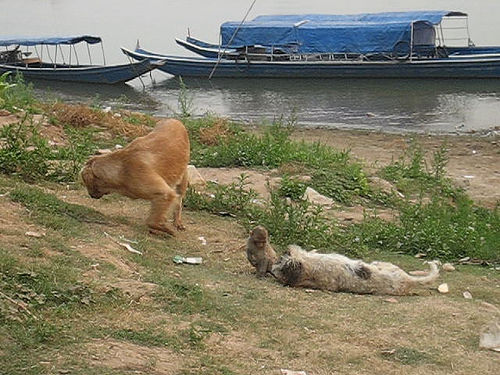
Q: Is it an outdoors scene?
A: Yes, it is outdoors.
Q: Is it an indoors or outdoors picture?
A: It is outdoors.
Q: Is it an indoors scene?
A: No, it is outdoors.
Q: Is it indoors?
A: No, it is outdoors.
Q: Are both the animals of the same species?
A: Yes, all the animals are dogs.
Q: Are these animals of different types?
A: No, all the animals are dogs.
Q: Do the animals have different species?
A: No, all the animals are dogs.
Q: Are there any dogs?
A: Yes, there is a dog.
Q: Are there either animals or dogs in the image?
A: Yes, there is a dog.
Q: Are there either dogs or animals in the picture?
A: Yes, there is a dog.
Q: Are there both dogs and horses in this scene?
A: No, there is a dog but no horses.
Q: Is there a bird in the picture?
A: No, there are no birds.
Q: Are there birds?
A: No, there are no birds.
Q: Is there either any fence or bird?
A: No, there are no birds or fences.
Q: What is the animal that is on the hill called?
A: The animal is a dog.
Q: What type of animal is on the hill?
A: The animal is a dog.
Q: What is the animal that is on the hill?
A: The animal is a dog.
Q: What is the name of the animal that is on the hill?
A: The animal is a dog.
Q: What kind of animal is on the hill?
A: The animal is a dog.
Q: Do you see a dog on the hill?
A: Yes, there is a dog on the hill.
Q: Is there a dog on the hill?
A: Yes, there is a dog on the hill.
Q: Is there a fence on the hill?
A: No, there is a dog on the hill.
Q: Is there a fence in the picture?
A: No, there are no fences.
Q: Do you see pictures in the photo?
A: No, there are no pictures.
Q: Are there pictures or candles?
A: No, there are no pictures or candles.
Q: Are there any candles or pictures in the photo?
A: No, there are no pictures or candles.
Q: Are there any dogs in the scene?
A: Yes, there is a dog.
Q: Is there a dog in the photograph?
A: Yes, there is a dog.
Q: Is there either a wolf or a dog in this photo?
A: Yes, there is a dog.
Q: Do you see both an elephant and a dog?
A: No, there is a dog but no elephants.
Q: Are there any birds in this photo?
A: No, there are no birds.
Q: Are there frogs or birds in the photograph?
A: No, there are no birds or frogs.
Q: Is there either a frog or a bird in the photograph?
A: No, there are no birds or frogs.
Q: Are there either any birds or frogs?
A: No, there are no birds or frogs.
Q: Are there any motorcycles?
A: No, there are no motorcycles.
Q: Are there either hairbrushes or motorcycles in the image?
A: No, there are no motorcycles or hairbrushes.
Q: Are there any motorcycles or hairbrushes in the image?
A: No, there are no motorcycles or hairbrushes.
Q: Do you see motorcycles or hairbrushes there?
A: No, there are no motorcycles or hairbrushes.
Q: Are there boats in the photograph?
A: Yes, there is a boat.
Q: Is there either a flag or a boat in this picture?
A: Yes, there is a boat.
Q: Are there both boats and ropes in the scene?
A: Yes, there are both a boat and a rope.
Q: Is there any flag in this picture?
A: No, there are no flags.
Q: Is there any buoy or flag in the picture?
A: No, there are no flags or buoys.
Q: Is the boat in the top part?
A: Yes, the boat is in the top of the image.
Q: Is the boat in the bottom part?
A: No, the boat is in the top of the image.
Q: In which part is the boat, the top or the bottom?
A: The boat is in the top of the image.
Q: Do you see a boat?
A: Yes, there is a boat.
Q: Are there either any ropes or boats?
A: Yes, there is a boat.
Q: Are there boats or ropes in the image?
A: Yes, there is a boat.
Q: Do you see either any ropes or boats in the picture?
A: Yes, there is a boat.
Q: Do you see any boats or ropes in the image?
A: Yes, there is a boat.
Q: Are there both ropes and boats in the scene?
A: Yes, there are both a boat and a rope.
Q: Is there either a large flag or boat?
A: Yes, there is a large boat.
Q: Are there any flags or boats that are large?
A: Yes, the boat is large.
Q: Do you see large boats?
A: Yes, there is a large boat.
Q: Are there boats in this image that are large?
A: Yes, there is a boat that is large.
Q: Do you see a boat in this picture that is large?
A: Yes, there is a boat that is large.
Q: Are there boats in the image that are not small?
A: Yes, there is a large boat.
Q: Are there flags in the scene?
A: No, there are no flags.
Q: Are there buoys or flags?
A: No, there are no flags or buoys.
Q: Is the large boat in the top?
A: Yes, the boat is in the top of the image.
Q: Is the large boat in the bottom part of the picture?
A: No, the boat is in the top of the image.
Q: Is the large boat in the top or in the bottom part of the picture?
A: The boat is in the top of the image.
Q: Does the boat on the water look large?
A: Yes, the boat is large.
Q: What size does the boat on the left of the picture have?
A: The boat has large size.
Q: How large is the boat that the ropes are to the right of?
A: The boat is large.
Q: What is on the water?
A: The boat is on the water.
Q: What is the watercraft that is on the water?
A: The watercraft is a boat.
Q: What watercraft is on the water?
A: The watercraft is a boat.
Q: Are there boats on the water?
A: Yes, there is a boat on the water.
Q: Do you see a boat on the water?
A: Yes, there is a boat on the water.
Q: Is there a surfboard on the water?
A: No, there is a boat on the water.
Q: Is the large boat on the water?
A: Yes, the boat is on the water.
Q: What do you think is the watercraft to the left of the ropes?
A: The watercraft is a boat.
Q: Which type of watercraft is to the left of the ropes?
A: The watercraft is a boat.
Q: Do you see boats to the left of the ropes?
A: Yes, there is a boat to the left of the ropes.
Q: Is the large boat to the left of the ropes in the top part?
A: Yes, the boat is to the left of the ropes.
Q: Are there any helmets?
A: No, there are no helmets.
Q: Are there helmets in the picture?
A: No, there are no helmets.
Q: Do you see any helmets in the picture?
A: No, there are no helmets.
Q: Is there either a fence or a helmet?
A: No, there are no helmets or fences.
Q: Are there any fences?
A: No, there are no fences.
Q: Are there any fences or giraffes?
A: No, there are no fences or giraffes.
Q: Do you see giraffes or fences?
A: No, there are no fences or giraffes.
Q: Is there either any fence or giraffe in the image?
A: No, there are no fences or giraffes.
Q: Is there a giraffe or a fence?
A: No, there are no fences or giraffes.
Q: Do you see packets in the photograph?
A: No, there are no packets.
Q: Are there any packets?
A: No, there are no packets.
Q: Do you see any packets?
A: No, there are no packets.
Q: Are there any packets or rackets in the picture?
A: No, there are no packets or rackets.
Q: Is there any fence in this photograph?
A: No, there are no fences.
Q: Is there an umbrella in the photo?
A: No, there are no umbrellas.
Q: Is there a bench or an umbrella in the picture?
A: No, there are no umbrellas or benches.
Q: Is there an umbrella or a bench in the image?
A: No, there are no umbrellas or benches.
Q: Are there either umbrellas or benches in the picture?
A: No, there are no umbrellas or benches.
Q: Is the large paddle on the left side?
A: Yes, the paddle is on the left of the image.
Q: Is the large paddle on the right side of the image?
A: No, the paddle is on the left of the image.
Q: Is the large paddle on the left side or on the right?
A: The oar is on the left of the image.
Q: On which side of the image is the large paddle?
A: The oar is on the left of the image.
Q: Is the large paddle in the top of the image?
A: Yes, the oar is in the top of the image.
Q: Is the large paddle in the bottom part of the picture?
A: No, the paddle is in the top of the image.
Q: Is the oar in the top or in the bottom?
A: The oar is in the top of the image.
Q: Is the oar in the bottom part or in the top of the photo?
A: The oar is in the top of the image.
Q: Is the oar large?
A: Yes, the oar is large.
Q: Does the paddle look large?
A: Yes, the paddle is large.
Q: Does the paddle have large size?
A: Yes, the paddle is large.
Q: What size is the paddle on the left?
A: The paddle is large.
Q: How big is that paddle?
A: The paddle is large.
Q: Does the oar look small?
A: No, the oar is large.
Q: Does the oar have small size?
A: No, the oar is large.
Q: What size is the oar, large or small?
A: The oar is large.